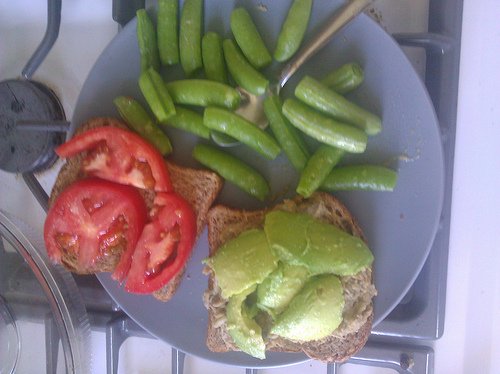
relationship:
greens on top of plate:
[81, 24, 408, 235] [46, 0, 450, 367]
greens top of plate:
[190, 142, 270, 197] [46, 0, 450, 367]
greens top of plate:
[280, 97, 365, 150] [46, 0, 450, 367]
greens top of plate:
[230, 7, 269, 67] [46, 0, 450, 367]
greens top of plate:
[136, 67, 174, 120] [46, 0, 450, 367]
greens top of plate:
[135, 7, 158, 69] [46, 0, 450, 367]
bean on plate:
[124, 9, 166, 75] [46, 0, 450, 367]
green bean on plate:
[317, 166, 393, 189] [348, 155, 439, 288]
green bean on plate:
[181, 2, 205, 72] [46, 0, 450, 367]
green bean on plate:
[136, 62, 176, 119] [46, 0, 450, 367]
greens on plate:
[278, 71, 386, 156] [46, 0, 450, 367]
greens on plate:
[136, 61, 248, 141] [46, 0, 450, 367]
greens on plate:
[192, 101, 281, 201] [46, 0, 450, 367]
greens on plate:
[129, 0, 206, 82] [46, 0, 450, 367]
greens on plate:
[222, 1, 314, 65] [46, 0, 450, 367]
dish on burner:
[66, 0, 446, 368] [1, 1, 463, 372]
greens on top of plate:
[135, 7, 158, 69] [46, 0, 450, 367]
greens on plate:
[135, 7, 158, 69] [54, 35, 440, 352]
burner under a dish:
[1, 1, 463, 372] [66, 0, 446, 368]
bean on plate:
[290, 137, 345, 199] [46, 0, 450, 367]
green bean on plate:
[199, 30, 226, 80] [46, 0, 450, 367]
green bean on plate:
[265, 102, 359, 155] [46, 0, 450, 367]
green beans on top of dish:
[115, 0, 398, 196] [66, 0, 446, 368]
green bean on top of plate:
[279, 97, 369, 156] [46, 0, 450, 367]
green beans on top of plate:
[132, 0, 393, 190] [46, 0, 450, 367]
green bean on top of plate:
[181, 131, 274, 211] [46, 0, 450, 367]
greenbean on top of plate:
[203, 105, 281, 159] [46, 0, 450, 367]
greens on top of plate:
[141, 35, 432, 227] [385, 49, 443, 318]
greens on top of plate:
[122, 24, 375, 194] [376, 91, 416, 125]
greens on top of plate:
[129, 8, 244, 98] [46, 0, 450, 367]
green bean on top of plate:
[220, 36, 270, 96] [46, 0, 450, 367]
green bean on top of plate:
[192, 141, 270, 199] [46, 0, 450, 367]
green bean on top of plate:
[293, 73, 382, 133] [46, 0, 450, 367]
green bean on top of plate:
[138, 62, 178, 123] [46, 0, 450, 367]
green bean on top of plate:
[229, 2, 271, 69] [46, 0, 450, 367]